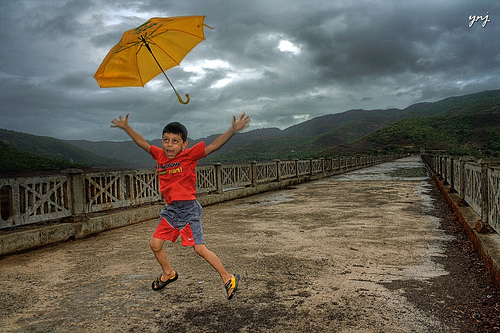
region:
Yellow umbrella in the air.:
[89, 13, 218, 108]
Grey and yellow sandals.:
[149, 270, 241, 298]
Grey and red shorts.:
[149, 202, 206, 245]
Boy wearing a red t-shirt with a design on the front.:
[148, 125, 215, 201]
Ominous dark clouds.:
[239, 4, 458, 114]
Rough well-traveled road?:
[309, 187, 443, 313]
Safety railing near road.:
[154, 116, 188, 161]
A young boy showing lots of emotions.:
[159, 124, 186, 159]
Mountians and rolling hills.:
[343, 105, 484, 149]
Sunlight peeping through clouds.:
[201, 54, 254, 93]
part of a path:
[351, 163, 363, 238]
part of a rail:
[466, 186, 472, 196]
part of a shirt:
[176, 176, 181, 187]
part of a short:
[187, 225, 192, 228]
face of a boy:
[165, 137, 185, 147]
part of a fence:
[52, 195, 73, 230]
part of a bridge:
[347, 204, 364, 230]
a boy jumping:
[107, 113, 250, 303]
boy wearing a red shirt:
[153, 160, 195, 200]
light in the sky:
[270, 33, 310, 60]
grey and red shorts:
[149, 205, 203, 245]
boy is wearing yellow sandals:
[219, 276, 242, 298]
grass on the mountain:
[11, 127, 44, 161]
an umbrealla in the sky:
[91, 13, 233, 112]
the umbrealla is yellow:
[91, 15, 211, 92]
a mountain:
[390, 111, 454, 147]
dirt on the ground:
[403, 275, 471, 320]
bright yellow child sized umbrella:
[92, 13, 214, 105]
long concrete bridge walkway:
[1, 151, 498, 331]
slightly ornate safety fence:
[2, 148, 412, 255]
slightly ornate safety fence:
[419, 146, 499, 288]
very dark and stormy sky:
[2, 0, 498, 141]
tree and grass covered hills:
[1, 88, 498, 222]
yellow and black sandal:
[221, 272, 241, 300]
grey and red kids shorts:
[151, 197, 207, 246]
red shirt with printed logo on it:
[149, 141, 208, 205]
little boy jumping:
[109, 108, 251, 298]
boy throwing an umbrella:
[87, 8, 274, 305]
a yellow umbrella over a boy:
[88, 9, 257, 311]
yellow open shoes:
[147, 266, 244, 304]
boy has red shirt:
[104, 108, 261, 303]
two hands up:
[96, 98, 261, 185]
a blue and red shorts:
[146, 199, 210, 251]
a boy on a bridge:
[16, 106, 498, 319]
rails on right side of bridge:
[367, 128, 496, 251]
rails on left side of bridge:
[228, 135, 385, 220]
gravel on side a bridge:
[396, 182, 496, 323]